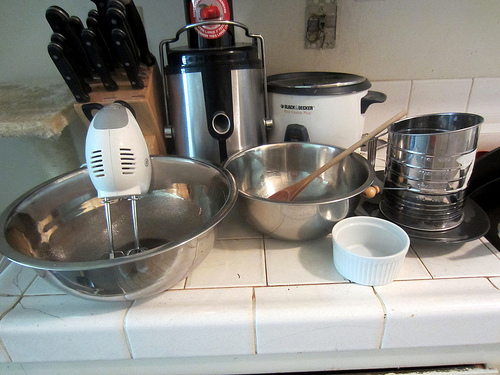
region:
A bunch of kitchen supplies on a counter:
[0, 1, 497, 342]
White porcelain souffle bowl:
[328, 214, 411, 286]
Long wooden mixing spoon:
[263, 109, 409, 215]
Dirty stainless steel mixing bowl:
[1, 153, 237, 303]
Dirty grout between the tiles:
[0, 219, 499, 364]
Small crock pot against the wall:
[261, 67, 389, 165]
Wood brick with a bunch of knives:
[33, 0, 171, 160]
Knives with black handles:
[36, 0, 160, 103]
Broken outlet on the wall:
[298, 0, 343, 57]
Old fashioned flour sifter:
[371, 103, 486, 233]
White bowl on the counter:
[317, 213, 418, 288]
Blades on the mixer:
[92, 195, 152, 282]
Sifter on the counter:
[363, 106, 493, 246]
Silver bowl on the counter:
[210, 137, 375, 248]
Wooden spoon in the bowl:
[265, 105, 410, 215]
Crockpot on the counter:
[257, 60, 392, 151]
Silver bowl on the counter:
[3, 146, 238, 316]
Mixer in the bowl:
[72, 100, 170, 272]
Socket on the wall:
[297, 1, 346, 63]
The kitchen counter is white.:
[225, 274, 317, 324]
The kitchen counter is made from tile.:
[216, 257, 313, 317]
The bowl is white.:
[328, 215, 412, 288]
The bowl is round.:
[330, 211, 407, 286]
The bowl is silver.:
[224, 133, 379, 240]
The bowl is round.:
[224, 143, 374, 245]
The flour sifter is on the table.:
[364, 108, 491, 233]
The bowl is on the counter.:
[324, 213, 419, 288]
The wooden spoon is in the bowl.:
[271, 111, 411, 206]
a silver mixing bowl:
[1, 150, 241, 302]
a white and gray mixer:
[74, 100, 159, 212]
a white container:
[331, 210, 411, 289]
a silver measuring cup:
[370, 101, 485, 237]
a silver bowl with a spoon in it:
[215, 140, 381, 250]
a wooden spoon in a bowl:
[266, 111, 412, 209]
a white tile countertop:
[16, 281, 488, 373]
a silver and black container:
[157, 13, 283, 164]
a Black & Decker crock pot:
[261, 62, 389, 150]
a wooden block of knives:
[30, 3, 160, 119]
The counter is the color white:
[198, 285, 475, 341]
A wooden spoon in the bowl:
[270, 89, 414, 210]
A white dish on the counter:
[327, 208, 414, 287]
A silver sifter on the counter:
[382, 105, 487, 234]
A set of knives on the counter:
[38, 5, 185, 161]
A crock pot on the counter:
[270, 63, 385, 153]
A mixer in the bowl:
[76, 97, 165, 266]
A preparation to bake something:
[13, 75, 494, 327]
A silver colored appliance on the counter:
[158, 15, 276, 173]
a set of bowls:
[9, 133, 370, 299]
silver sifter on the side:
[369, 105, 480, 250]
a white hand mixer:
[60, 98, 145, 263]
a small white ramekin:
[326, 205, 411, 293]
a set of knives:
[32, 0, 143, 97]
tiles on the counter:
[198, 255, 337, 345]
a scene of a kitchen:
[21, 35, 499, 321]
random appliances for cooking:
[2, 4, 494, 324]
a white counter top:
[7, 174, 497, 372]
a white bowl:
[310, 198, 427, 296]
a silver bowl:
[208, 140, 384, 242]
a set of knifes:
[32, 6, 179, 165]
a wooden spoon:
[258, 105, 415, 217]